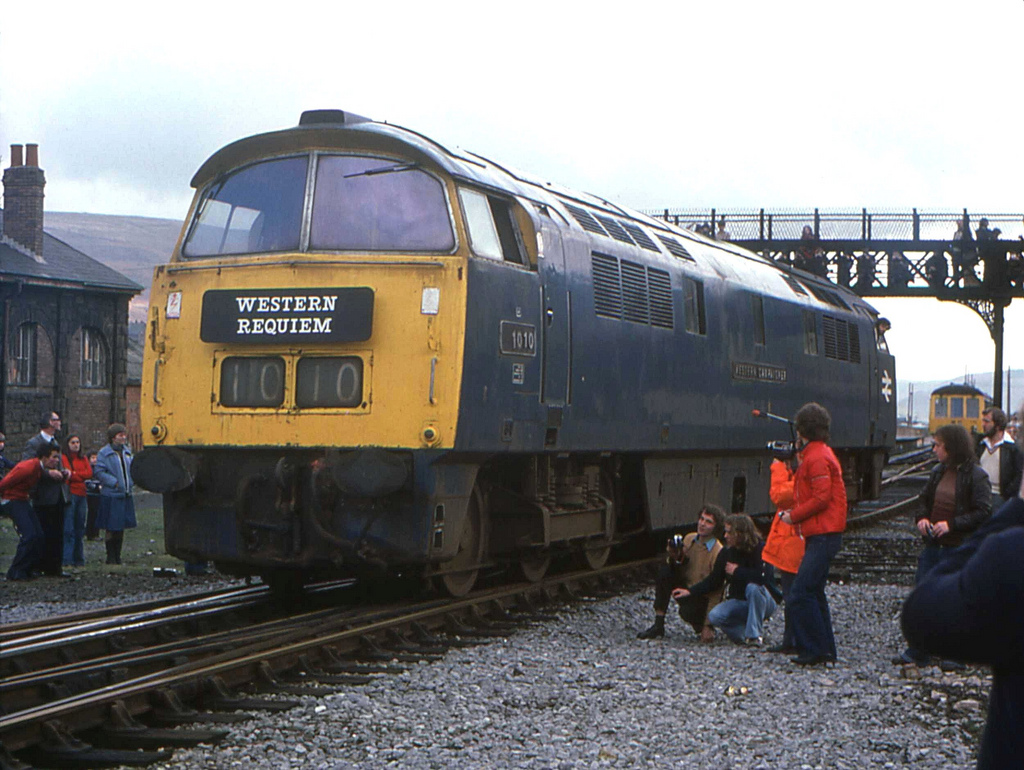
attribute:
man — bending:
[12, 434, 70, 585]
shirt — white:
[976, 436, 1013, 494]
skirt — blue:
[96, 494, 142, 532]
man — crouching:
[644, 501, 721, 635]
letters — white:
[228, 285, 350, 343]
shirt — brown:
[942, 486, 968, 569]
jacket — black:
[963, 455, 992, 587]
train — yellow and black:
[942, 378, 981, 404]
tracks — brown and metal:
[33, 596, 118, 728]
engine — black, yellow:
[544, 227, 666, 457]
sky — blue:
[2, 3, 990, 211]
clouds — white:
[386, 16, 642, 114]